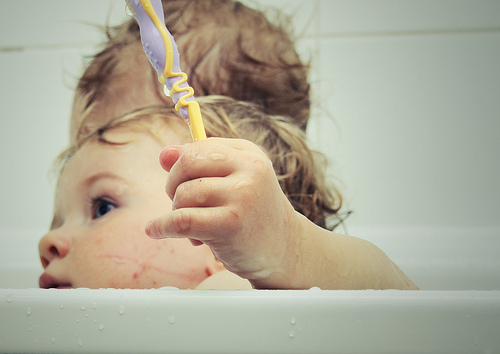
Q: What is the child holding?
A: Tooth brush.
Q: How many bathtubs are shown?
A: 1.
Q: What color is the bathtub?
A: White.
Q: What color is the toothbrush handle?
A: Yellow and purple.